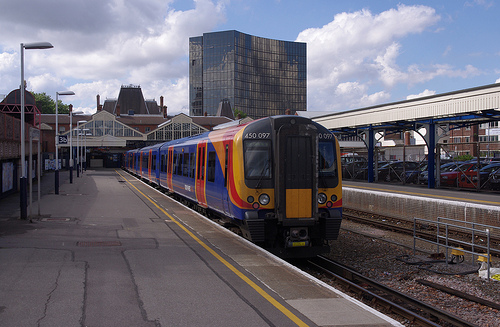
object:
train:
[121, 113, 348, 259]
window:
[493, 134, 498, 143]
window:
[204, 150, 216, 183]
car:
[373, 158, 426, 184]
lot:
[340, 159, 498, 190]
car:
[436, 159, 481, 186]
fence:
[410, 214, 500, 285]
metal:
[410, 217, 439, 223]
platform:
[0, 166, 408, 327]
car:
[473, 163, 499, 192]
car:
[357, 160, 394, 182]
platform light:
[20, 41, 54, 51]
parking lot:
[339, 147, 499, 192]